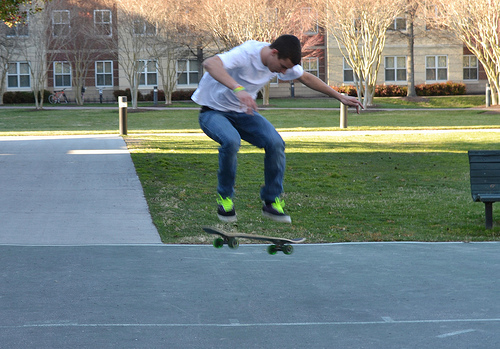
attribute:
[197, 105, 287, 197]
jeans — blue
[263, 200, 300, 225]
shoe — blue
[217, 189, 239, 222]
shoe — blue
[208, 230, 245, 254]
tires — black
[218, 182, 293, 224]
sneakers —  Black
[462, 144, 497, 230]
bench —  grey ,  wooden,  park's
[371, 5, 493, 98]
tree — leafless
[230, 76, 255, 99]
wristband — green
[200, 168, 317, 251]
skate shoes — black, white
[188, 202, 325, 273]
skate board — black, white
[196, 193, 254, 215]
laces — green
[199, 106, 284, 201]
jeans — blue 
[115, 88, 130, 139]
pole — wooden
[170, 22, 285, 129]
shirt — white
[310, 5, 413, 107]
tree —  with no leaves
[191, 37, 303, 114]
white shirt — cotton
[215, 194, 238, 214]
laces — green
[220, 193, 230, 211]
shoelaces —  green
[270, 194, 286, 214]
laces — green